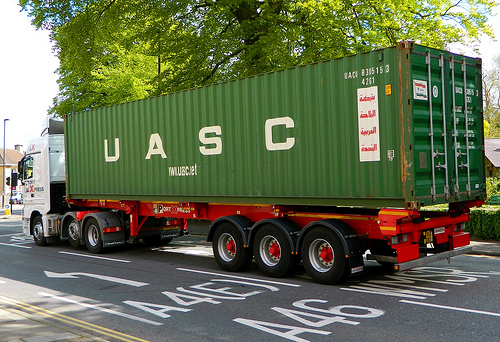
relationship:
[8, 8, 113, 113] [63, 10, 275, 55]
sky beside tree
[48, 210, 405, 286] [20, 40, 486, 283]
black wheels on truck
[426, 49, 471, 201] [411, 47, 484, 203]
bars on wall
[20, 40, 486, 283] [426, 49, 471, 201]
truck has bars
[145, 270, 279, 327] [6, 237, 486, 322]
pavement with lines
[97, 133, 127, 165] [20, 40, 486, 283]
letter on truck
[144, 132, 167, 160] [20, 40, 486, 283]
letter on truck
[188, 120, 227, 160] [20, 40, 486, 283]
letter on truck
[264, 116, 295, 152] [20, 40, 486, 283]
letter on truck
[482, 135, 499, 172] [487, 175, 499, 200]
house in back of hedges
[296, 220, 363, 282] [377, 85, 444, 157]
tire on truck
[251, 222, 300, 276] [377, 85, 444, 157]
tire on truck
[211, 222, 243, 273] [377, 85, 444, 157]
wheel on truck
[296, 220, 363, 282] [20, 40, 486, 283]
tire on truck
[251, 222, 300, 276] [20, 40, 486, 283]
tire on truck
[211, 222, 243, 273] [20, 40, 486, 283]
wheel on truck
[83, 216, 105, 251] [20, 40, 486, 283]
wheel on truck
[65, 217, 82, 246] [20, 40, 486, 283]
wheel on truck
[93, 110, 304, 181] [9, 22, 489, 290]
name on truck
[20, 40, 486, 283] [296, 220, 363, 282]
truck has tire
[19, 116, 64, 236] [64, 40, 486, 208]
cab in from of container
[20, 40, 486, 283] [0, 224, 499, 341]
truck driving on road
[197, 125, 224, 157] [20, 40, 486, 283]
letter on truck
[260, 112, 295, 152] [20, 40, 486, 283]
letter on truck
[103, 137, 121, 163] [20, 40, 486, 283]
letter on truck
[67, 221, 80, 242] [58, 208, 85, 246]
rim on wheel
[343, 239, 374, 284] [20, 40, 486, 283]
mudflap on truck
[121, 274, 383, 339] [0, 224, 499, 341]
letters/numbers on road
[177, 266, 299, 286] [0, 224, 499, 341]
line on road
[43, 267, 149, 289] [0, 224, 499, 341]
white arrow on road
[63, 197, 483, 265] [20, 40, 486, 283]
bed on truck